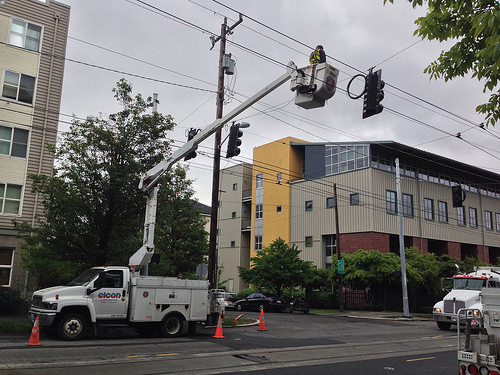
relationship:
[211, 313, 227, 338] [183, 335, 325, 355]
cones on ground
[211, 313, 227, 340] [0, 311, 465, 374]
cones on at pavement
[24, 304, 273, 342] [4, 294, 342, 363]
cones on street